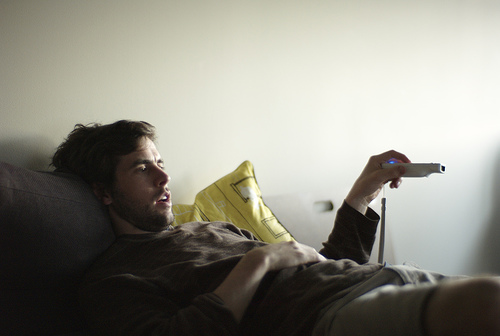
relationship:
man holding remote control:
[113, 128, 185, 275] [372, 129, 452, 183]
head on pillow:
[107, 125, 209, 245] [35, 177, 97, 256]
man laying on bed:
[45, 121, 499, 336] [3, 161, 484, 331]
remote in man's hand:
[383, 159, 448, 179] [349, 145, 412, 205]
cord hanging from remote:
[376, 188, 390, 264] [381, 157, 446, 179]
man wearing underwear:
[45, 121, 499, 336] [314, 260, 447, 332]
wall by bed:
[2, 4, 483, 153] [4, 152, 399, 332]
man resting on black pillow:
[45, 121, 499, 336] [3, 162, 107, 324]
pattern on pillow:
[229, 172, 257, 202] [169, 160, 292, 243]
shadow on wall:
[3, 130, 57, 166] [6, 3, 388, 115]